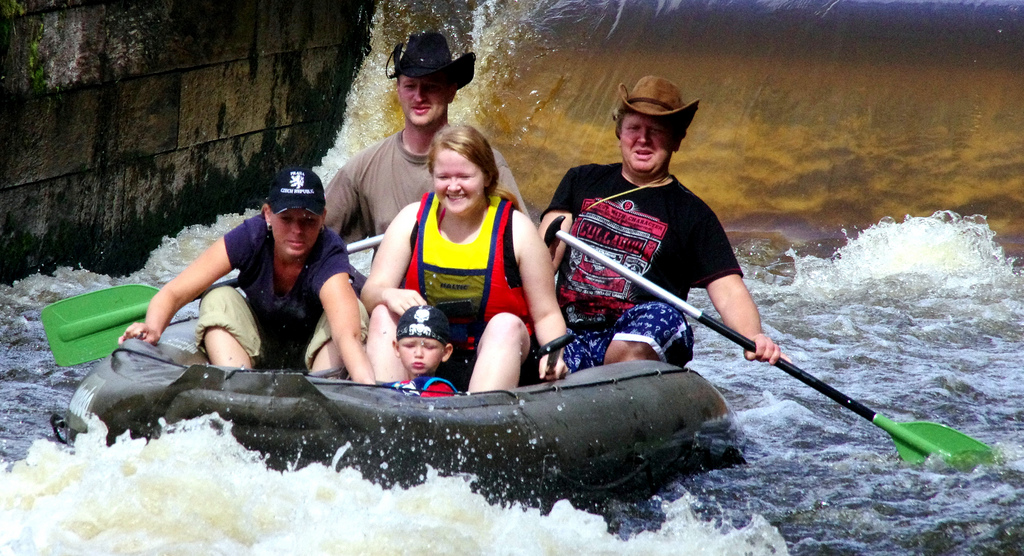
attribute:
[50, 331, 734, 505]
raft — black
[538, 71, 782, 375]
person — rubber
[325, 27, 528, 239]
person — riding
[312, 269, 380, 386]
arm — white, human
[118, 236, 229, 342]
arm — white, human arm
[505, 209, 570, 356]
white arm1 — human arm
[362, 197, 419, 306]
white arm2 — human arm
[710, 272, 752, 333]
white arm — human arm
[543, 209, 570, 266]
white arm — human arm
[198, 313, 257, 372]
white leg — human leg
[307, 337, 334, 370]
white leg — human leg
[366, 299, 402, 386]
white leg — human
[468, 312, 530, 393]
white leg — human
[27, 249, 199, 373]
oar1 — green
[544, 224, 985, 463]
oar2 — green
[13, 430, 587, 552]
wave — small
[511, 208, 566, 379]
arm — white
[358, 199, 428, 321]
arm — white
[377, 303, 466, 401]
child — young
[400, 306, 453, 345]
cap — baseball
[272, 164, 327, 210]
cap — baseball